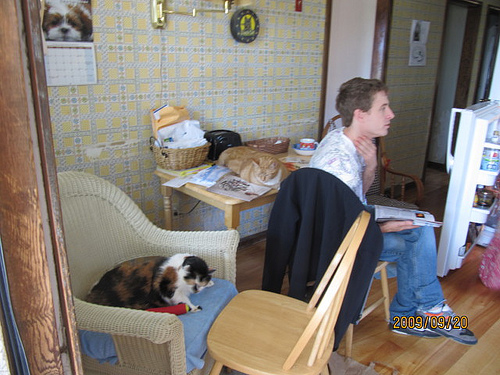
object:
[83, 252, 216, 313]
cat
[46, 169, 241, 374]
chair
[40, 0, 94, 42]
dog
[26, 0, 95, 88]
calender